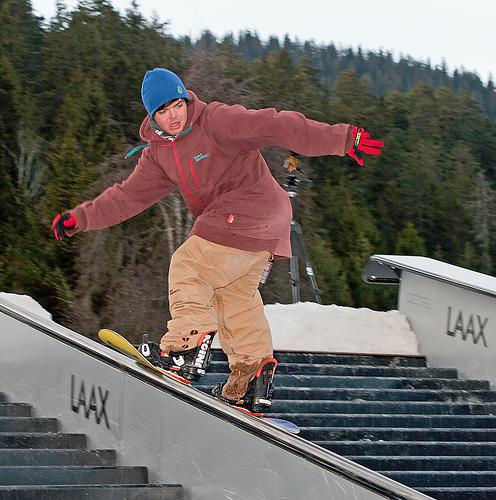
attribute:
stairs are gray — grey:
[0, 334, 189, 499]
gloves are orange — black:
[343, 117, 387, 176]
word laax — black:
[434, 301, 494, 353]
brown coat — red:
[71, 112, 360, 269]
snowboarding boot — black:
[213, 352, 304, 418]